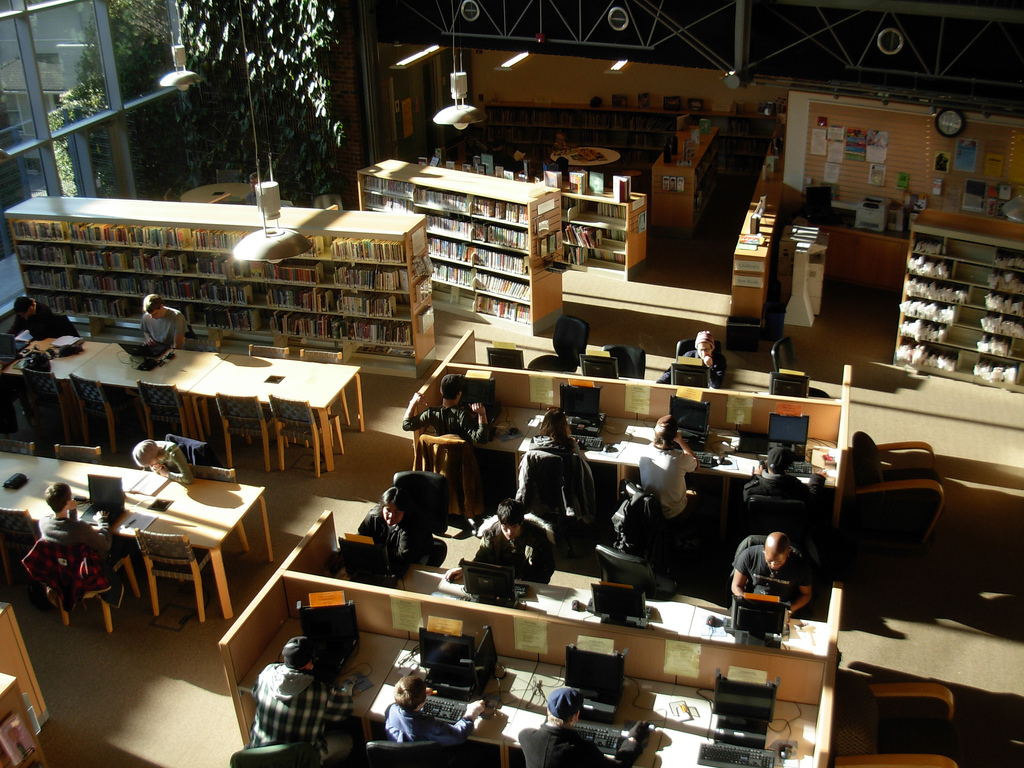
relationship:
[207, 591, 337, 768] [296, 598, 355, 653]
man using a computer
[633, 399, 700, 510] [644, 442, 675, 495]
man wearing a beige shirt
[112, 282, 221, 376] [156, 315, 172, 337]
man wearing a gray shirt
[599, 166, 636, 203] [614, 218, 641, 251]
book standing on bookshelf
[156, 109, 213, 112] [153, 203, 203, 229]
light hanging above table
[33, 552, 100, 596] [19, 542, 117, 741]
jacket on back of a chair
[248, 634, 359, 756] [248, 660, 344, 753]
man wearing shirt